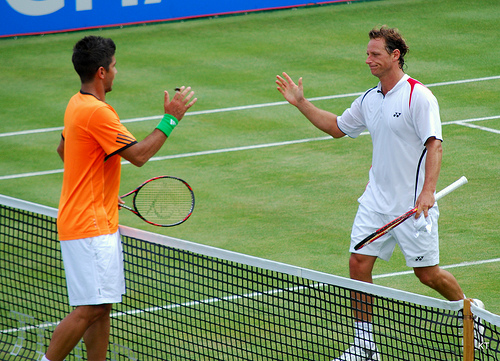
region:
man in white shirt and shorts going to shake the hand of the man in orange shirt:
[266, 24, 488, 357]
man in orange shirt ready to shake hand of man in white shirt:
[26, 28, 201, 359]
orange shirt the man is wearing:
[53, 87, 139, 242]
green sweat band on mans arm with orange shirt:
[146, 109, 181, 138]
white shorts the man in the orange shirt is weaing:
[49, 226, 131, 313]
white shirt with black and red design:
[329, 74, 446, 220]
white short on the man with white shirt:
[342, 207, 447, 274]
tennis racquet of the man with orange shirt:
[120, 173, 197, 235]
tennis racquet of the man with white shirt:
[351, 173, 468, 252]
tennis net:
[1, 187, 498, 358]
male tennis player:
[36, 31, 198, 359]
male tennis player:
[270, 24, 496, 357]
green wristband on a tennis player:
[154, 111, 180, 139]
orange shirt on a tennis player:
[55, 89, 138, 244]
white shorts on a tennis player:
[57, 229, 132, 306]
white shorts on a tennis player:
[347, 201, 442, 268]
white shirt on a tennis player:
[333, 73, 444, 219]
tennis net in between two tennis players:
[2, 191, 497, 359]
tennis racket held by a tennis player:
[116, 170, 198, 229]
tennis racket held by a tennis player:
[350, 170, 469, 250]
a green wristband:
[157, 114, 181, 135]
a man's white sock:
[348, 315, 375, 345]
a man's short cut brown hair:
[368, 25, 408, 62]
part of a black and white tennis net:
[127, 222, 498, 359]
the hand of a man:
[270, 70, 307, 107]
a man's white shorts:
[351, 200, 448, 270]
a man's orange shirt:
[50, 93, 137, 240]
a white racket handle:
[435, 174, 466, 204]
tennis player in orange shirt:
[36, 33, 197, 358]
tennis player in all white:
[270, 22, 485, 357]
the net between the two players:
[0, 192, 497, 357]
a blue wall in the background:
[0, 0, 355, 35]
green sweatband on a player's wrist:
[150, 110, 175, 135]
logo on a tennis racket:
[141, 176, 178, 216]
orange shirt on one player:
[55, 87, 135, 237]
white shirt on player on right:
[335, 71, 441, 211]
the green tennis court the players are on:
[0, 0, 497, 360]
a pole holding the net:
[461, 295, 471, 360]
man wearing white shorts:
[39, 219, 137, 314]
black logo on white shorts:
[413, 248, 427, 265]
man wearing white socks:
[351, 315, 379, 350]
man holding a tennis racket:
[98, 180, 211, 233]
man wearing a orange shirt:
[40, 85, 145, 235]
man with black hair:
[63, 29, 132, 95]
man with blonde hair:
[356, 29, 410, 80]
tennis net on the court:
[1, 197, 494, 353]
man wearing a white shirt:
[339, 66, 444, 198]